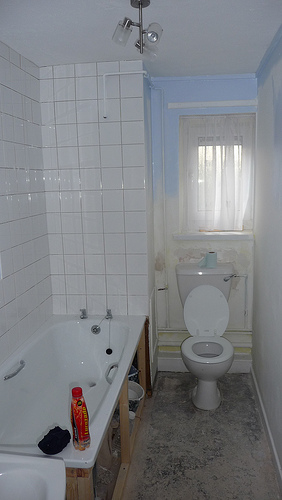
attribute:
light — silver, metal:
[110, 1, 163, 54]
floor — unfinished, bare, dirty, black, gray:
[121, 369, 281, 498]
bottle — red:
[71, 389, 92, 450]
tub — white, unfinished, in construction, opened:
[1, 308, 150, 499]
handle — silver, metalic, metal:
[104, 357, 117, 385]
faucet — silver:
[77, 308, 112, 322]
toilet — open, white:
[177, 264, 234, 411]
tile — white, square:
[1, 43, 150, 371]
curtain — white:
[179, 115, 254, 229]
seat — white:
[179, 335, 234, 365]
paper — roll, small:
[199, 251, 217, 267]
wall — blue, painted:
[151, 74, 256, 371]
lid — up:
[182, 283, 230, 336]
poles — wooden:
[67, 317, 150, 499]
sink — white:
[1, 450, 67, 500]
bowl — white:
[182, 343, 233, 380]